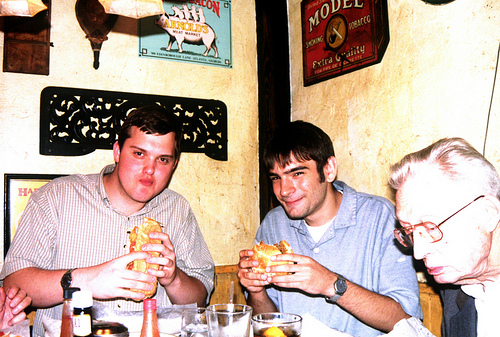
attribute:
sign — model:
[301, 0, 388, 86]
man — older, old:
[388, 140, 498, 333]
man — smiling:
[15, 69, 181, 308]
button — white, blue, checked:
[310, 243, 321, 255]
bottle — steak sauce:
[67, 287, 95, 334]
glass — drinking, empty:
[206, 300, 253, 335]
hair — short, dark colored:
[117, 104, 188, 150]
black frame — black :
[4, 172, 9, 259]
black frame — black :
[2, 172, 70, 179]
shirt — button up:
[22, 165, 217, 331]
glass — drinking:
[238, 307, 298, 334]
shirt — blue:
[239, 188, 414, 335]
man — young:
[237, 120, 423, 335]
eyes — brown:
[270, 170, 305, 178]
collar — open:
[91, 162, 160, 224]